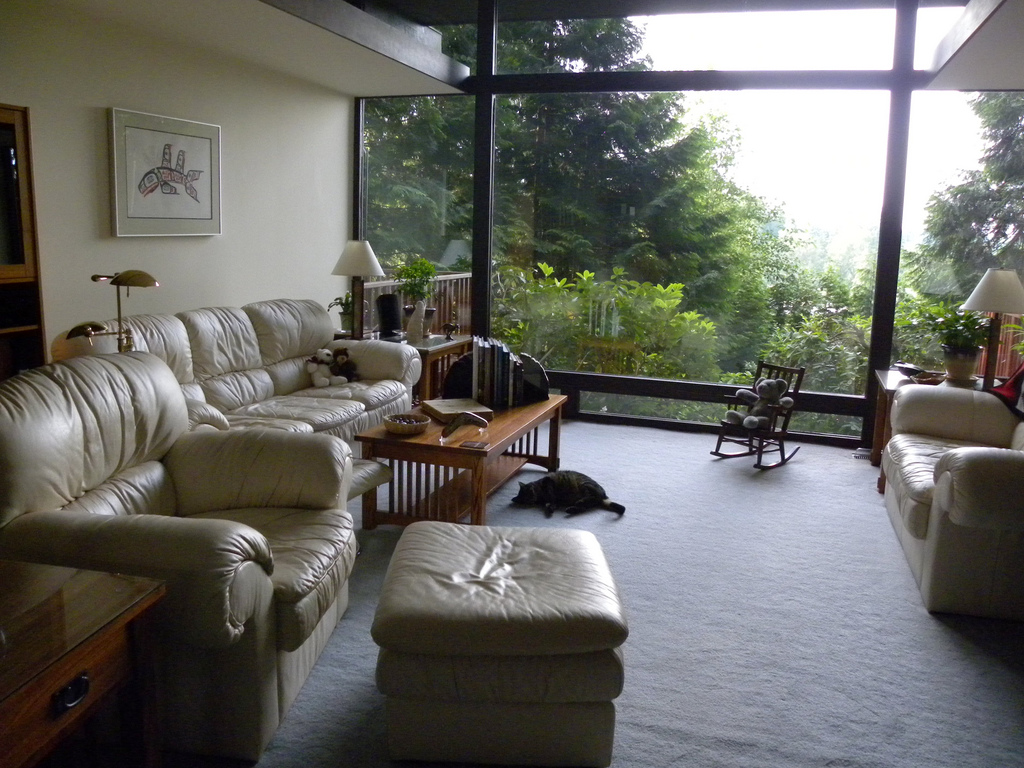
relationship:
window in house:
[471, 71, 911, 449] [2, 5, 1023, 762]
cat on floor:
[505, 465, 632, 524] [157, 394, 1013, 758]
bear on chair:
[725, 378, 793, 426] [700, 358, 809, 472]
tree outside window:
[550, 17, 744, 293] [495, 31, 922, 436]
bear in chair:
[725, 377, 794, 428] [710, 362, 806, 471]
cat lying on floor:
[510, 470, 623, 515] [255, 419, 1022, 768]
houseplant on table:
[922, 307, 987, 383] [861, 348, 1007, 412]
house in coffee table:
[0, 0, 1022, 768] [353, 393, 567, 529]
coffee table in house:
[353, 393, 567, 529] [0, 0, 1022, 768]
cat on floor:
[510, 470, 623, 515] [548, 447, 1005, 751]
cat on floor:
[510, 470, 623, 515] [612, 444, 1011, 746]